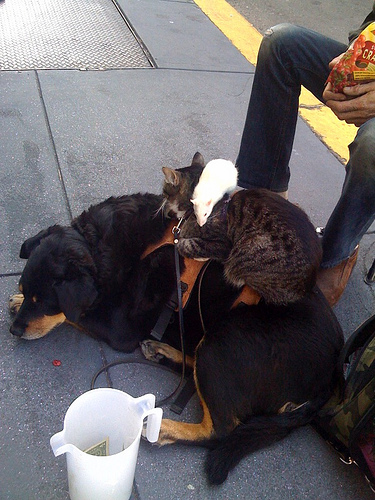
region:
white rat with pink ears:
[186, 193, 264, 228]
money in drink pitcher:
[41, 374, 176, 498]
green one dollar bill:
[74, 421, 119, 477]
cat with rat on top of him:
[166, 148, 326, 329]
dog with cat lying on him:
[4, 184, 343, 417]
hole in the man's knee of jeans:
[260, 22, 295, 54]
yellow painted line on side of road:
[215, 11, 256, 57]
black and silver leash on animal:
[171, 218, 191, 379]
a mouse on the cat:
[153, 155, 290, 286]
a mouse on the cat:
[145, 148, 232, 260]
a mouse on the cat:
[137, 135, 267, 285]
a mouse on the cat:
[145, 155, 234, 255]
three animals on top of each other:
[12, 149, 337, 497]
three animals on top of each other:
[11, 156, 299, 433]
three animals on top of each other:
[11, 123, 332, 488]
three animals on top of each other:
[14, 131, 323, 449]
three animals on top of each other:
[11, 135, 310, 469]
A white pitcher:
[49, 386, 162, 497]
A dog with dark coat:
[8, 192, 344, 487]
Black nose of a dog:
[8, 327, 25, 335]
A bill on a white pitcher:
[83, 436, 108, 456]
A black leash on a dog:
[92, 230, 187, 405]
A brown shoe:
[316, 248, 359, 307]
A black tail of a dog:
[203, 373, 343, 482]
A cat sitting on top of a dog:
[154, 151, 323, 303]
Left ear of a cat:
[162, 166, 179, 183]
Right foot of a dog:
[141, 339, 179, 363]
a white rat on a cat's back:
[189, 155, 238, 229]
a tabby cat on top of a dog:
[160, 151, 324, 304]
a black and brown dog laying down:
[8, 190, 344, 483]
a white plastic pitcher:
[47, 386, 163, 498]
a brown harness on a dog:
[141, 213, 200, 342]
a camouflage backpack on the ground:
[318, 313, 374, 491]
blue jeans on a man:
[237, 24, 373, 263]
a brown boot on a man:
[316, 244, 363, 302]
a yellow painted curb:
[195, 1, 360, 167]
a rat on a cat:
[88, 159, 355, 334]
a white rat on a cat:
[165, 151, 322, 256]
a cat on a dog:
[72, 153, 333, 329]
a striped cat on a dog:
[155, 155, 340, 335]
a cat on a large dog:
[94, 169, 367, 383]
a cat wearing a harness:
[147, 157, 347, 326]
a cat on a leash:
[123, 151, 367, 324]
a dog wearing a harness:
[35, 170, 367, 436]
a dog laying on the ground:
[33, 201, 372, 459]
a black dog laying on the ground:
[13, 194, 367, 490]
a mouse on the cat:
[172, 144, 226, 215]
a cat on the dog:
[151, 162, 257, 292]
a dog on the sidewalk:
[30, 200, 347, 467]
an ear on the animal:
[47, 273, 111, 315]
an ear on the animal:
[22, 222, 58, 261]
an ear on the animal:
[187, 199, 197, 205]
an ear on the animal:
[157, 166, 186, 186]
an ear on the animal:
[187, 142, 207, 166]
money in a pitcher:
[74, 425, 128, 493]